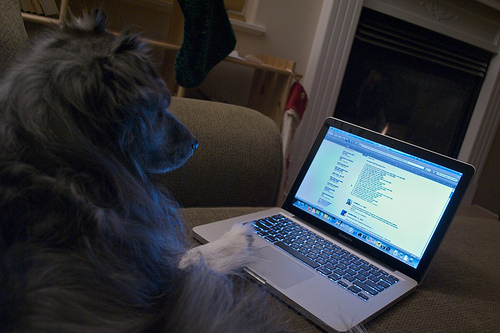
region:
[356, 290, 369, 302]
black button on computer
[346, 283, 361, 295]
black button on computer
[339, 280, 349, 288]
black button on computer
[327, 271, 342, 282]
black button on computer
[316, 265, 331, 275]
black button on computer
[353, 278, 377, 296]
black button on computer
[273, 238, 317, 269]
black button on computer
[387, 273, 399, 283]
black button on computer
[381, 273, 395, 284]
black button on computer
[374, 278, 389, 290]
black button on computer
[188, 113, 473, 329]
a silver laptop computer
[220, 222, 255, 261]
the paw of a dog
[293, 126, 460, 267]
a computer screen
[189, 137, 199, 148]
nose of a dog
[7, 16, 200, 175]
dog has a head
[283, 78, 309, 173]
a stocking is hanging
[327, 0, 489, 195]
a fireplace is lit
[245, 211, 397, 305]
a laptop computer keyboard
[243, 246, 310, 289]
trackpad on a laptop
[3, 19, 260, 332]
a black and white dog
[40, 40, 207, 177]
head of a dog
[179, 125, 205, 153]
nose of a dog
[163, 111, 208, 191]
mouth of a dog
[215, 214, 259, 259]
leg of a dog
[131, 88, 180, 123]
eye of a dog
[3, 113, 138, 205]
neck of a dog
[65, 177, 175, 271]
fur of a dog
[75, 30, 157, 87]
hair of a dog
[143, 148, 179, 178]
jaw of a dog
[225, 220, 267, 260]
paw of a dog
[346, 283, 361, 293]
Black and white button on a keyboard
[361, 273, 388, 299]
Black and white button on a keyboard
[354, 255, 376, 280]
Black and white button on a keyboard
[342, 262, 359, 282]
Black and white button on a keyboard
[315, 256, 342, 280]
Black and white button on a keyboard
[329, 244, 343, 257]
Black and white button on a keyboard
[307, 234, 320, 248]
Black and white button on a keyboard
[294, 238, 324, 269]
Black and white button on a keyboard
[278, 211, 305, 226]
Black and white button on a keyboard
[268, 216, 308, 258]
Black and white button on a keyboard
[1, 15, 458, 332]
dog with paw on laptop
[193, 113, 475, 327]
laptop with display turned on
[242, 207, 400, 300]
illuminated laptop keyboard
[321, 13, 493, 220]
fireplace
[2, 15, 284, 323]
dog is laying on the couch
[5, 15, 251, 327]
dog has fluffy dark fur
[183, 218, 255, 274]
dog has white paw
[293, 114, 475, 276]
computer displays a webpage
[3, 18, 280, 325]
couch is a shade of brown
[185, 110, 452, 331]
laptop has silver base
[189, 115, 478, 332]
a white and black lap top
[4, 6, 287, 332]
a black dog with white paws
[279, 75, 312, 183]
a white and red bag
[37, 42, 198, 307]
gray and white dog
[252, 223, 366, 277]
blue light below keyboard